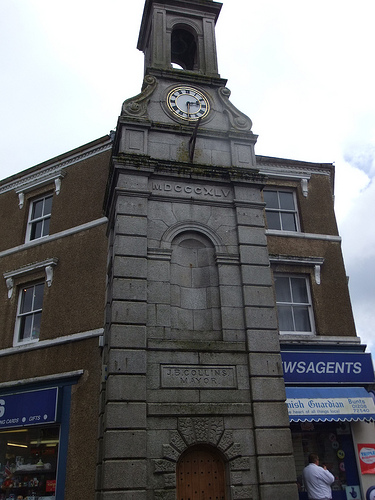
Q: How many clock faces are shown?
A: One.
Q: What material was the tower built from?
A: Stone.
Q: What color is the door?
A: Brown.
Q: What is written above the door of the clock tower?
A: J.B. COLLINS MAYOR.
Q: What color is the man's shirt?
A: White.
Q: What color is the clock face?
A: White.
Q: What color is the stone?
A: Grey.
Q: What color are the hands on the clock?
A: Black.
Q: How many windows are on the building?
A: Four.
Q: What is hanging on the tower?
A: Clock.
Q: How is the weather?
A: Cloudy.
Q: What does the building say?
A: J. B. Collins Mayor.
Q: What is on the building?
A: A clock.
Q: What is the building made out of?
A: Stone.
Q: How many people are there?
A: One.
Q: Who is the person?
A: A man.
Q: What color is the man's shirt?
A: White.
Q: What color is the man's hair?
A: Brown.